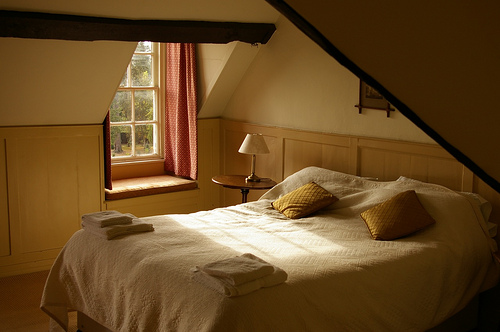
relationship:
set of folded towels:
[191, 253, 288, 299] [190, 254, 289, 298]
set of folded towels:
[80, 211, 155, 241] [82, 210, 154, 240]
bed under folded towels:
[40, 167, 500, 331] [190, 254, 289, 298]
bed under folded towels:
[40, 167, 500, 331] [82, 210, 154, 240]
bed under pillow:
[40, 167, 500, 331] [358, 190, 435, 243]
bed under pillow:
[40, 167, 500, 331] [271, 181, 338, 218]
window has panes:
[109, 41, 167, 165] [110, 42, 155, 158]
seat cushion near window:
[104, 174, 197, 201] [109, 41, 167, 165]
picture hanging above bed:
[353, 77, 396, 118] [40, 167, 500, 331]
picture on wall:
[353, 77, 396, 118] [220, 14, 499, 262]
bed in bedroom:
[40, 167, 500, 331] [1, 1, 500, 331]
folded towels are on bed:
[190, 254, 289, 298] [40, 167, 500, 331]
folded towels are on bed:
[82, 210, 154, 240] [40, 167, 500, 331]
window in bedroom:
[109, 41, 167, 165] [1, 1, 500, 331]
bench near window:
[103, 173, 199, 204] [109, 41, 167, 165]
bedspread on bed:
[40, 166, 500, 330] [40, 167, 500, 331]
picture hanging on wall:
[353, 77, 396, 118] [220, 14, 499, 262]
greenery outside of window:
[109, 42, 155, 157] [109, 41, 167, 165]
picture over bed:
[353, 77, 396, 118] [40, 167, 500, 331]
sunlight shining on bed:
[170, 203, 349, 265] [40, 167, 500, 331]